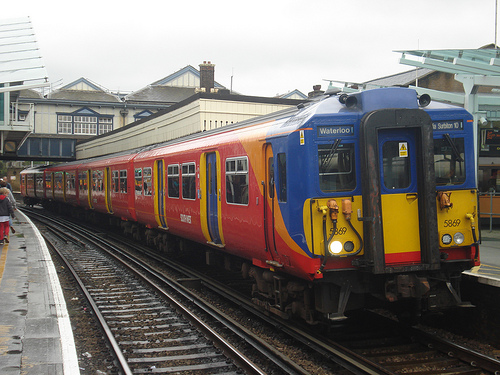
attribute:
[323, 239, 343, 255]
headlight — lit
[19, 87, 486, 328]
train — blue yelloow, red, big, multicolored, blue, yellow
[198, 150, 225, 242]
door — blue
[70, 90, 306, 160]
building — white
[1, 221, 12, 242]
pants — red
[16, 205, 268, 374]
tracks — metallic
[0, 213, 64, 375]
bricks — grey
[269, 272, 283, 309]
ladder — small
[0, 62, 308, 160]
building — tan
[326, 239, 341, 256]
light — lit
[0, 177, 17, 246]
people — standing, walking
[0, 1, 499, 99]
sky — overcast, cloudy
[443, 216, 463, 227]
train number — 5869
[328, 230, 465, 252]
headlights — lit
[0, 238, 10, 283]
stripe — yellow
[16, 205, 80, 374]
edge — white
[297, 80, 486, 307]
front — flat